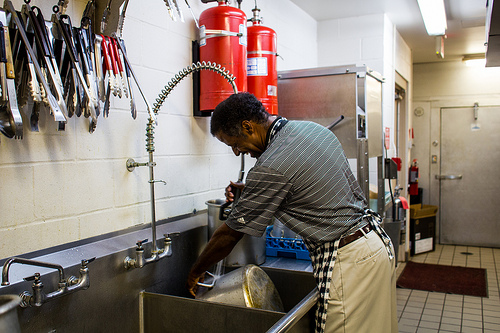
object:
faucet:
[118, 232, 178, 270]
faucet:
[0, 252, 94, 307]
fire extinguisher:
[244, 6, 280, 123]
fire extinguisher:
[194, 0, 253, 114]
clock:
[414, 106, 425, 118]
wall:
[413, 61, 498, 245]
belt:
[325, 218, 381, 251]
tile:
[422, 306, 442, 316]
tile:
[398, 314, 423, 328]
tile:
[482, 313, 499, 326]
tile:
[452, 259, 467, 267]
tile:
[423, 254, 440, 264]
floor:
[387, 241, 499, 332]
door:
[436, 107, 498, 247]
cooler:
[428, 99, 498, 251]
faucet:
[125, 61, 260, 269]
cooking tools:
[0, 0, 32, 142]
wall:
[0, 1, 321, 264]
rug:
[398, 258, 489, 300]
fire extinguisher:
[408, 158, 419, 195]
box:
[409, 204, 438, 257]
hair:
[210, 91, 271, 138]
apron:
[265, 113, 408, 331]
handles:
[98, 30, 112, 77]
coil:
[146, 59, 246, 194]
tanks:
[195, 6, 247, 112]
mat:
[388, 249, 490, 303]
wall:
[112, 4, 323, 209]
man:
[207, 91, 417, 332]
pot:
[188, 268, 295, 313]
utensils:
[45, 9, 98, 131]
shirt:
[226, 119, 369, 238]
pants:
[319, 228, 404, 332]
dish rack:
[266, 225, 314, 264]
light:
[417, 0, 450, 36]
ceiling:
[298, 0, 497, 51]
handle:
[435, 173, 462, 180]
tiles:
[409, 290, 485, 320]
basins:
[49, 268, 293, 333]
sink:
[18, 210, 315, 330]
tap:
[126, 58, 263, 195]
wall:
[6, 1, 372, 224]